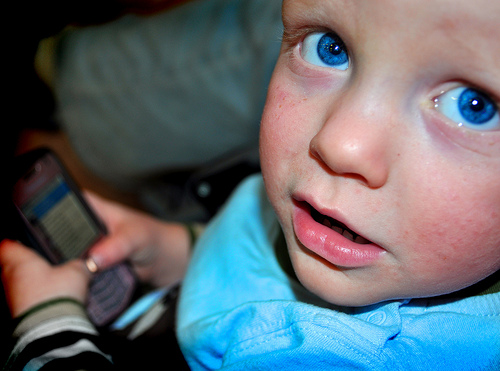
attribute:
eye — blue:
[297, 29, 352, 71]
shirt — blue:
[180, 170, 499, 368]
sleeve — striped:
[180, 218, 209, 260]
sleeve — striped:
[6, 291, 121, 370]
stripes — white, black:
[186, 218, 210, 247]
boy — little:
[2, 0, 499, 366]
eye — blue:
[429, 83, 499, 133]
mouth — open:
[286, 188, 387, 269]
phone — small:
[4, 141, 138, 334]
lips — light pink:
[277, 184, 427, 287]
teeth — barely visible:
[300, 205, 375, 256]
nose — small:
[309, 105, 390, 195]